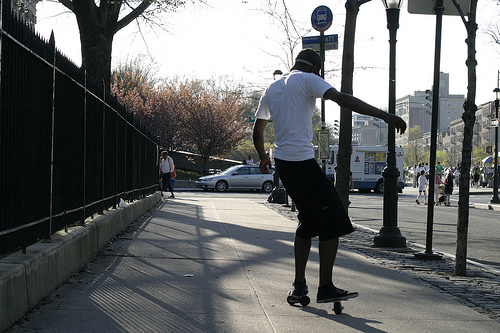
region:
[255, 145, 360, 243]
man wearing black shorts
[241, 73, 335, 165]
man wearing a white tee shirt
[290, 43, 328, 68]
man wearing a black hat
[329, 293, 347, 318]
man with a wheel on his shoe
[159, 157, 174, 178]
man wearing a white shirt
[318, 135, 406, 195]
ice cream truck on the curb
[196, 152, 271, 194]
car parked on the corner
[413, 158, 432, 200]
child crossing the street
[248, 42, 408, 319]
A guy is skateboarding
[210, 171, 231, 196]
A black round tire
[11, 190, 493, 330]
Shadows on the ground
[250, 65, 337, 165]
A white colored shirt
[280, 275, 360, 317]
Two feet on a skateboard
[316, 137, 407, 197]
A white truck on the road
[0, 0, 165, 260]
A black iron fence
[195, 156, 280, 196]
The side of a silver car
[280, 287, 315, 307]
Two wheels on a skateboard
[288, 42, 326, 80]
Hat on a guy's head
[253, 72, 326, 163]
short sleeve white shirt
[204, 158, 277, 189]
white car on the street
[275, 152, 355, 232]
black shorts the man is wearing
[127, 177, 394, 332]
shadows on the sidewalk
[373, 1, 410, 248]
street lamp on the sidewalk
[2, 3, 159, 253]
black fence along the sidewalk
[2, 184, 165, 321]
cement base of the fence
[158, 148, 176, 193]
man walking on the sidewalk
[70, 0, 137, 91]
large tree behind the black fence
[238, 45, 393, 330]
a man riding shoes with wheels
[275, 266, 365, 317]
shoes with wheels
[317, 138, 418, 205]
a truck parked on the side of the road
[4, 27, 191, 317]
a fence by the side of a street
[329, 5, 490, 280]
light poles and sign poles on the side of the street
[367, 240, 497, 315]
a line of cobblestone on the street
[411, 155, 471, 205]
a group of people on the street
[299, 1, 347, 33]
a blue and white sign of a bus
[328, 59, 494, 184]
buildings by the side of the street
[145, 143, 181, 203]
a person standing by a fence